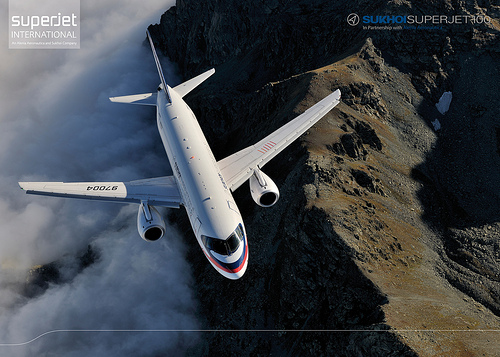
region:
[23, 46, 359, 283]
Red white and blue plane flying over mountain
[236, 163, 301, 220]
engine on a plane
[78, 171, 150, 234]
plane number 97004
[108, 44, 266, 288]
plane soaring in the sky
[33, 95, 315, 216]
plane over the clouds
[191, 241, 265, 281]
Plane with blue and red paint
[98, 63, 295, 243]
Plane in the sky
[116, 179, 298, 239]
Plane with two engines on it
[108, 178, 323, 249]
Plane flying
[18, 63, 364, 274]
a white plane flying through the sky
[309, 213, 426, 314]
brown dirt peak of a mountain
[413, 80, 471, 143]
snow in a crevice of the mountain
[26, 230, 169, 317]
fluffy white clouds on the side of the mountain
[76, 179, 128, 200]
black numbers on the wing of the plane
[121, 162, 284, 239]
twin engines of the plane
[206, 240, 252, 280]
red white and blue nose of the plane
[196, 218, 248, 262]
black windshield of the plane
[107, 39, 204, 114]
white tail fins of the plane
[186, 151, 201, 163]
red light on the top of the plane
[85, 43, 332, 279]
Airplane flying over the mountains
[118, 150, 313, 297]
Airplane flying over the mountains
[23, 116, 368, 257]
Airplane flying over the mountains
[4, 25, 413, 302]
a white plane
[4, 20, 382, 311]
the plane is in the air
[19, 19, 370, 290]
the plane is on top of clouds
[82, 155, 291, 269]
the plane has two engines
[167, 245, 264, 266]
it is painted on the front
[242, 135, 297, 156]
the wing also has red stripes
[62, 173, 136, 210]
the wing has nnumbers on it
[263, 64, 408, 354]
the mountain is brown in colour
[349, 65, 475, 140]
there are white stones on the base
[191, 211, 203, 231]
its door is locked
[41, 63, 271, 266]
Plane soaring through the sky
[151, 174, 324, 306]
plane flying in the sky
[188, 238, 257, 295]
Blue and red paint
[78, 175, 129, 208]
97004 on a plane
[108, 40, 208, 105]
Tail on the plane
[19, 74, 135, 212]
Clouds under the plane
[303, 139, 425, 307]
mountain under the plane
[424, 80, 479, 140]
snow on the mountain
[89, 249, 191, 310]
clouds on the mountain